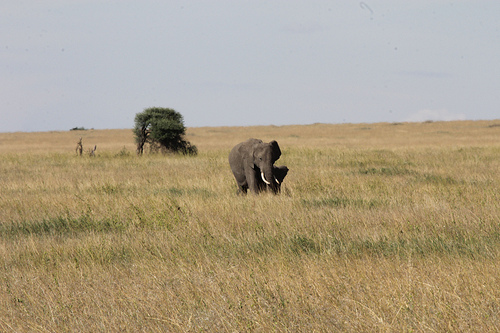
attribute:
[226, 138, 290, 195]
elephant — lone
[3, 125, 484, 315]
area — grassy, plains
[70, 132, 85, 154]
trunk — tree, rotten, old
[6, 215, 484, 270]
grass — green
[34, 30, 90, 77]
clouds — white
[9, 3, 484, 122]
sky — blue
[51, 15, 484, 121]
sky — blue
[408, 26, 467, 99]
clouds — white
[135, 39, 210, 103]
clouds — white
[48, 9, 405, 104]
sky — blue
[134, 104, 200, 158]
tree — leafy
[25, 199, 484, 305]
grass — a lot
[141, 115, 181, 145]
leaves — many, green, tree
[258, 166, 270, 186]
tusk — elephant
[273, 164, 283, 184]
tusk — elephant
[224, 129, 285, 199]
elephant — bull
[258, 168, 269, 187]
tusk — white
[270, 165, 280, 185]
tusk — white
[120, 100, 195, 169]
tree — green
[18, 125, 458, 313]
grass — dry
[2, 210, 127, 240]
grass — green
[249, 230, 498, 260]
grass — green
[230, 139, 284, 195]
elephant — gray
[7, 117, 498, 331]
grass — brown and green 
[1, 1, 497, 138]
sky — blue, cloudless